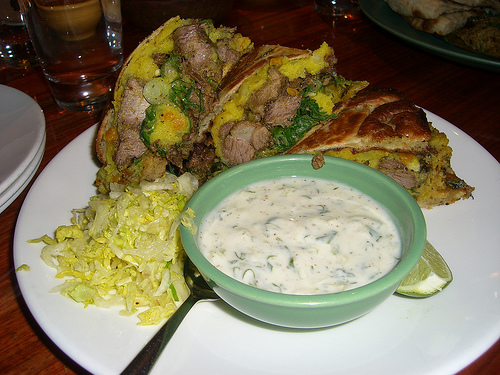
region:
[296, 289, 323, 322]
edge of a dish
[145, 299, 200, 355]
part of a ha dle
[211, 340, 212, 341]
part of a handle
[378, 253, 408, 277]
edge of a dish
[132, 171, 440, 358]
this is some yogurt sauce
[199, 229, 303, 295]
the sauce is white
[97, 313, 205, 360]
this is a utensil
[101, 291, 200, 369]
the spoon is silver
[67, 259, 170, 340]
the spoon is metal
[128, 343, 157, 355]
this is a spoon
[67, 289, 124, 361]
this is a plate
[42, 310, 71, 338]
the plate is white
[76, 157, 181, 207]
this is some yellow rice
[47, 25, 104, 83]
this is a glass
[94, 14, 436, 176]
it is a sanweg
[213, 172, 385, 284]
it is curd in cup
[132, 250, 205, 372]
it is a silver spoon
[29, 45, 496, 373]
it is a white color plate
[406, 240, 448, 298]
it is green lamon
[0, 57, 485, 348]
four white color plates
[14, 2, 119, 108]
it is a glass in the table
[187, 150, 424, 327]
cup color is green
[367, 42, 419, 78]
it is brown color table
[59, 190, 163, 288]
food color is yellow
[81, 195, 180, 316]
cabbage is green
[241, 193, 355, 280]
milk is in the bowl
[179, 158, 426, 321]
the bowl is green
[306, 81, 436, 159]
the meat is cooked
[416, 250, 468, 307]
the lemon is half cut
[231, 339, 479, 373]
the plate is white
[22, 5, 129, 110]
glass is on the table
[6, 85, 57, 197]
the plates are three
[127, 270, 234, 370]
spoon is on the plate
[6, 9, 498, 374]
the scene was taken indoors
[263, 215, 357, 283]
the soup is thick and white in color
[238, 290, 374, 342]
the bowel is green in color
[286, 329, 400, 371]
the plate is white in color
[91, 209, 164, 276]
the foods are gren yelow in color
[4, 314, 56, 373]
the table is brwon in color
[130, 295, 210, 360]
the spoon is silvery in color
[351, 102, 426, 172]
the pizza are brown in color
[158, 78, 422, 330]
the food is delicious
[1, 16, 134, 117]
the glasses have brown drinks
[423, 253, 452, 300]
ha quater piece of an orange